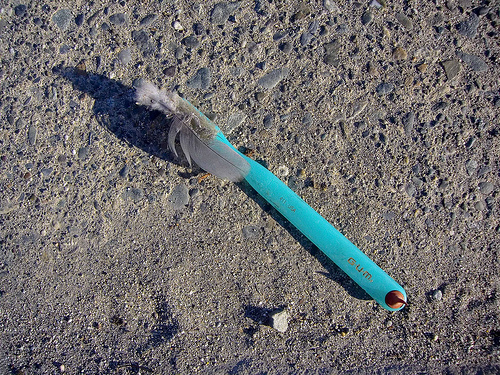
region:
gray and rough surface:
[15, 10, 477, 366]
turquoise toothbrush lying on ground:
[135, 75, 410, 315]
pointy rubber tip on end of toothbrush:
[380, 286, 406, 308]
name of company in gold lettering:
[325, 241, 375, 281]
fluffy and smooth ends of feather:
[125, 75, 245, 185]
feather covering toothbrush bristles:
[130, 75, 245, 190]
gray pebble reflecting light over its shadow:
[240, 296, 295, 332]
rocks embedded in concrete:
[200, 10, 480, 107]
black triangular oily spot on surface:
[136, 291, 181, 352]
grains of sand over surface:
[50, 321, 461, 362]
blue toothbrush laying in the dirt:
[115, 62, 495, 328]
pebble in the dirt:
[270, 295, 295, 331]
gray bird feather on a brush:
[125, 66, 255, 177]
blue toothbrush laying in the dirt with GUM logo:
[119, 68, 439, 328]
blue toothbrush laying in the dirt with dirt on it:
[133, 62, 438, 324]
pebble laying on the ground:
[260, 313, 302, 331]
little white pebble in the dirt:
[168, 15, 188, 32]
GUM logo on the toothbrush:
[338, 245, 383, 288]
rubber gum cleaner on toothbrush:
[379, 288, 407, 313]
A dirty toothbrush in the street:
[130, 74, 412, 316]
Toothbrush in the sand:
[118, 63, 447, 343]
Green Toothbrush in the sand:
[122, 68, 432, 351]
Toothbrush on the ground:
[129, 79, 419, 315]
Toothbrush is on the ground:
[125, 77, 417, 319]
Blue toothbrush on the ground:
[127, 76, 412, 321]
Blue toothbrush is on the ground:
[128, 76, 415, 317]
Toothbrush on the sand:
[130, 75, 413, 317]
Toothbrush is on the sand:
[127, 74, 415, 319]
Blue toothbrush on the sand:
[126, 71, 415, 323]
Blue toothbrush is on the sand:
[130, 77, 414, 318]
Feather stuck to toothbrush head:
[132, 76, 261, 190]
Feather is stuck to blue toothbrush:
[132, 77, 249, 184]